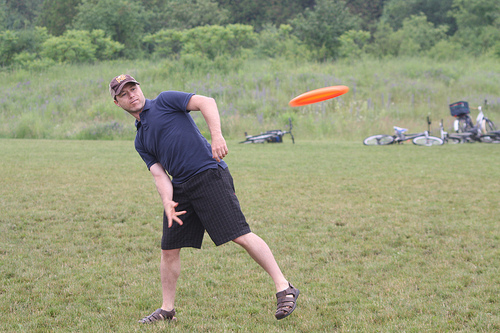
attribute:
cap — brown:
[110, 75, 140, 88]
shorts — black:
[151, 166, 254, 254]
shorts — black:
[160, 165, 248, 250]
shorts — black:
[155, 152, 240, 241]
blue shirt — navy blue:
[132, 91, 228, 179]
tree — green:
[10, 24, 132, 80]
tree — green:
[134, 22, 313, 69]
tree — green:
[328, 13, 486, 70]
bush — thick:
[4, 1, 499, 76]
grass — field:
[0, 136, 497, 331]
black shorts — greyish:
[159, 165, 253, 250]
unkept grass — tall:
[27, 56, 145, 157]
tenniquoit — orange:
[285, 85, 350, 108]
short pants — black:
[155, 164, 250, 246]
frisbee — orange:
[286, 81, 356, 113]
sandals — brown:
[259, 283, 300, 317]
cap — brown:
[108, 68, 143, 95]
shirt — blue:
[124, 86, 219, 182]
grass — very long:
[11, 58, 497, 123]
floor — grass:
[10, 135, 476, 329]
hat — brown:
[111, 74, 140, 98]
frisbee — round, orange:
[288, 85, 353, 107]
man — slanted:
[89, 71, 273, 275]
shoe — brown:
[273, 282, 300, 319]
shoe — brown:
[136, 307, 177, 322]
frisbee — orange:
[290, 82, 348, 107]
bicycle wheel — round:
[409, 131, 445, 146]